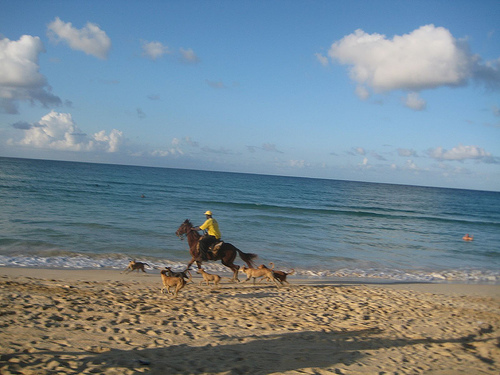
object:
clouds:
[326, 22, 471, 96]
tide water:
[2, 248, 499, 289]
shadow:
[2, 322, 497, 373]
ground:
[1, 285, 498, 362]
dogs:
[163, 267, 195, 283]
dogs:
[120, 257, 153, 276]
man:
[191, 209, 220, 260]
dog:
[196, 268, 221, 288]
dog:
[157, 263, 189, 298]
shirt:
[198, 216, 221, 240]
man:
[461, 231, 475, 243]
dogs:
[256, 263, 293, 285]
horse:
[174, 215, 257, 282]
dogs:
[238, 263, 284, 290]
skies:
[1, 0, 500, 191]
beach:
[0, 260, 498, 373]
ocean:
[0, 152, 497, 282]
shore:
[0, 257, 499, 299]